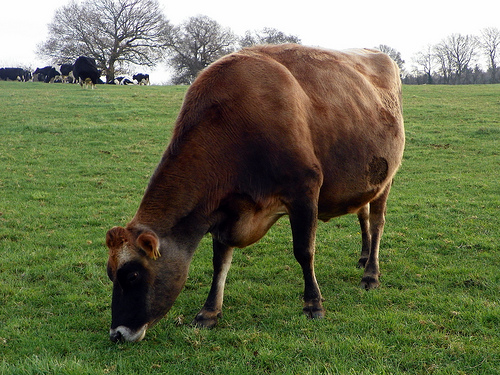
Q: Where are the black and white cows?
A: Behind the brown cow.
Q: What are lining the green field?
A: Trees.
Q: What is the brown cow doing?
A: Eating grass.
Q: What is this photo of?
A: A field.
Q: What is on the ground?
A: Green grass.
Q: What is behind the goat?
A: A herd.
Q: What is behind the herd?
A: Tall trees.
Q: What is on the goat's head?
A: White hair.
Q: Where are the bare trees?
A: Near the black and white cows.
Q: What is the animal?
A: A cow.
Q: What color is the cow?
A: Brown.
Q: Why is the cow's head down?
A: To eat.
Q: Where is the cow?
A: A field.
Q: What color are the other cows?
A: Black.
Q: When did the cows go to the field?
A: This morning.